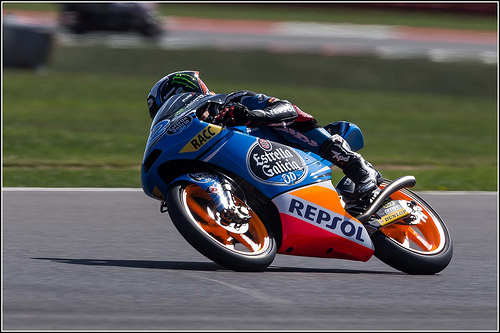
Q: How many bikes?
A: 1.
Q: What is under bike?
A: Road.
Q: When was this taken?
A: Daytime.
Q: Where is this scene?
A: On a track.